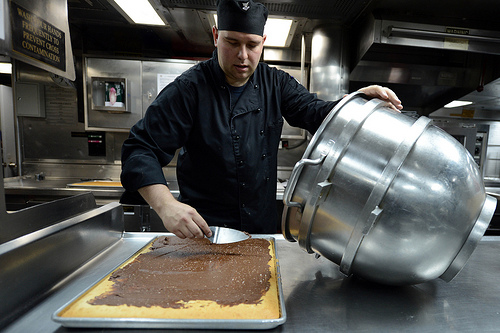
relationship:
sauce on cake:
[127, 246, 273, 297] [57, 232, 278, 322]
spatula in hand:
[195, 226, 250, 244] [141, 191, 216, 245]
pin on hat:
[233, 0, 265, 21] [211, 6, 295, 48]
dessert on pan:
[39, 150, 148, 192] [47, 188, 124, 205]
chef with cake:
[135, 0, 325, 255] [57, 232, 278, 322]